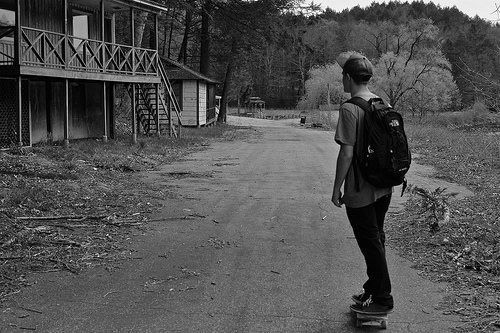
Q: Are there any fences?
A: No, there are no fences.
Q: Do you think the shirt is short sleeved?
A: Yes, the shirt is short sleeved.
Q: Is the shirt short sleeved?
A: Yes, the shirt is short sleeved.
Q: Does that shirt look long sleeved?
A: No, the shirt is short sleeved.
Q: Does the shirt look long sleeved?
A: No, the shirt is short sleeved.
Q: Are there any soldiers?
A: No, there are no soldiers.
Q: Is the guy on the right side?
A: Yes, the guy is on the right of the image.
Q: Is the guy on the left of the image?
A: No, the guy is on the right of the image.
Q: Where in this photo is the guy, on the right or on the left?
A: The guy is on the right of the image.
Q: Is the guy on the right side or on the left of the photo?
A: The guy is on the right of the image.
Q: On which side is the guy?
A: The guy is on the right of the image.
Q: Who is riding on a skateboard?
A: The guy is riding on a skateboard.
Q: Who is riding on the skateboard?
A: The guy is riding on a skateboard.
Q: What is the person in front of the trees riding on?
A: The guy is riding on a skateboard.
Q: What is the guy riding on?
A: The guy is riding on a skateboard.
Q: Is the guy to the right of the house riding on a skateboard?
A: Yes, the guy is riding on a skateboard.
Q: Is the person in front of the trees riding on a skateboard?
A: Yes, the guy is riding on a skateboard.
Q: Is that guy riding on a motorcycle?
A: No, the guy is riding on a skateboard.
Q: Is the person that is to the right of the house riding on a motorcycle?
A: No, the guy is riding on a skateboard.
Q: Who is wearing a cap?
A: The guy is wearing a cap.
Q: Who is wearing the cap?
A: The guy is wearing a cap.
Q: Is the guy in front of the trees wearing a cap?
A: Yes, the guy is wearing a cap.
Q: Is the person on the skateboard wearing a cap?
A: Yes, the guy is wearing a cap.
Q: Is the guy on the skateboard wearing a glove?
A: No, the guy is wearing a cap.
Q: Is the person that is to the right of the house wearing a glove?
A: No, the guy is wearing a cap.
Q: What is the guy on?
A: The guy is on the skateboard.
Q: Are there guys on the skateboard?
A: Yes, there is a guy on the skateboard.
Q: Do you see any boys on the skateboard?
A: No, there is a guy on the skateboard.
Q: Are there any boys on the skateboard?
A: No, there is a guy on the skateboard.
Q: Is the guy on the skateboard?
A: Yes, the guy is on the skateboard.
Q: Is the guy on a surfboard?
A: No, the guy is on the skateboard.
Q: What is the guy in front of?
A: The guy is in front of the trees.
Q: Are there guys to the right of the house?
A: Yes, there is a guy to the right of the house.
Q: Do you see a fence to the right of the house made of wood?
A: No, there is a guy to the right of the house.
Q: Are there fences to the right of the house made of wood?
A: No, there is a guy to the right of the house.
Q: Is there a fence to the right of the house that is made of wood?
A: No, there is a guy to the right of the house.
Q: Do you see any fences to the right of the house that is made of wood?
A: No, there is a guy to the right of the house.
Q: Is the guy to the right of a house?
A: Yes, the guy is to the right of a house.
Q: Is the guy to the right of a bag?
A: No, the guy is to the right of a house.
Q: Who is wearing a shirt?
A: The guy is wearing a shirt.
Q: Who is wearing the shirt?
A: The guy is wearing a shirt.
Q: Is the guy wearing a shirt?
A: Yes, the guy is wearing a shirt.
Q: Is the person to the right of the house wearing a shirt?
A: Yes, the guy is wearing a shirt.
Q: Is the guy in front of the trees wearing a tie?
A: No, the guy is wearing a shirt.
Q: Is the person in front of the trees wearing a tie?
A: No, the guy is wearing a shirt.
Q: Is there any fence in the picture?
A: No, there are no fences.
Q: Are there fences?
A: No, there are no fences.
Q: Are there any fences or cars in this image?
A: No, there are no fences or cars.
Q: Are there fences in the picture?
A: No, there are no fences.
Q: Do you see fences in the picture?
A: No, there are no fences.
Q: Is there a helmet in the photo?
A: No, there are no helmets.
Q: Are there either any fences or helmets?
A: No, there are no helmets or fences.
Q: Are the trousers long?
A: Yes, the trousers are long.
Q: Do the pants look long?
A: Yes, the pants are long.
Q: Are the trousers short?
A: No, the trousers are long.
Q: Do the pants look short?
A: No, the pants are long.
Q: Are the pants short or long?
A: The pants are long.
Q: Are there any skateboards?
A: Yes, there is a skateboard.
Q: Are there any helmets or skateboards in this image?
A: Yes, there is a skateboard.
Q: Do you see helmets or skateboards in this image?
A: Yes, there is a skateboard.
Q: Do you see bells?
A: No, there are no bells.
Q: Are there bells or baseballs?
A: No, there are no bells or baseballs.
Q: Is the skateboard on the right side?
A: Yes, the skateboard is on the right of the image.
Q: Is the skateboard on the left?
A: No, the skateboard is on the right of the image.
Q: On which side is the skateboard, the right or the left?
A: The skateboard is on the right of the image.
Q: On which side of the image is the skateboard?
A: The skateboard is on the right of the image.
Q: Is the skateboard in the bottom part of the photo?
A: Yes, the skateboard is in the bottom of the image.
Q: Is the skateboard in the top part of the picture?
A: No, the skateboard is in the bottom of the image.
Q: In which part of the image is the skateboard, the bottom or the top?
A: The skateboard is in the bottom of the image.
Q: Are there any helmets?
A: No, there are no helmets.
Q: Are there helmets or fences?
A: No, there are no helmets or fences.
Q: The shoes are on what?
A: The shoes are on the skateboard.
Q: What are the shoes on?
A: The shoes are on the skateboard.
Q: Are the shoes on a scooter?
A: No, the shoes are on the skateboard.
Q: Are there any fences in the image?
A: No, there are no fences.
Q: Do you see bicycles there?
A: No, there are no bicycles.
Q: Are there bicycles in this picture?
A: No, there are no bicycles.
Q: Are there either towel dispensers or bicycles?
A: No, there are no bicycles or towel dispensers.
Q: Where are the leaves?
A: The leaves are on the ground.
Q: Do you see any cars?
A: No, there are no cars.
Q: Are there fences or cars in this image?
A: No, there are no cars or fences.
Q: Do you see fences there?
A: No, there are no fences.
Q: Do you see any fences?
A: No, there are no fences.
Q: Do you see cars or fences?
A: No, there are no fences or cars.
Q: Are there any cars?
A: No, there are no cars.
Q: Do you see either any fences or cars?
A: No, there are no cars or fences.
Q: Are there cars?
A: No, there are no cars.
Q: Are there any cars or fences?
A: No, there are no cars or fences.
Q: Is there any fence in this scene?
A: No, there are no fences.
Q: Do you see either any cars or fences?
A: No, there are no fences or cars.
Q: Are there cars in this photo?
A: No, there are no cars.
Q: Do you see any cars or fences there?
A: No, there are no cars or fences.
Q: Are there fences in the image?
A: No, there are no fences.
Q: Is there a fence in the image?
A: No, there are no fences.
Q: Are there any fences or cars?
A: No, there are no fences or cars.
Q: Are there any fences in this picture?
A: No, there are no fences.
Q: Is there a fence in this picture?
A: No, there are no fences.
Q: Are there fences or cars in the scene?
A: No, there are no cars or fences.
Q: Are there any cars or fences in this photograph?
A: No, there are no cars or fences.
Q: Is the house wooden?
A: Yes, the house is wooden.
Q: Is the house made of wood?
A: Yes, the house is made of wood.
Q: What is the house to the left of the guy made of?
A: The house is made of wood.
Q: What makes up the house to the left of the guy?
A: The house is made of wood.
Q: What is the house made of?
A: The house is made of wood.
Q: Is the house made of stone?
A: No, the house is made of wood.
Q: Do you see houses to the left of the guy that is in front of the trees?
A: Yes, there is a house to the left of the guy.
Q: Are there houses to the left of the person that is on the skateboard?
A: Yes, there is a house to the left of the guy.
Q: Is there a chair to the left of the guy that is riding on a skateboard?
A: No, there is a house to the left of the guy.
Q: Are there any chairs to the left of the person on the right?
A: No, there is a house to the left of the guy.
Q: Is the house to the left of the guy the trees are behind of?
A: Yes, the house is to the left of the guy.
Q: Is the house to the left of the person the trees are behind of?
A: Yes, the house is to the left of the guy.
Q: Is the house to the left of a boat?
A: No, the house is to the left of the guy.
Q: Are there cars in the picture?
A: No, there are no cars.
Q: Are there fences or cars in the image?
A: No, there are no cars or fences.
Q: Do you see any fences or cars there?
A: No, there are no cars or fences.